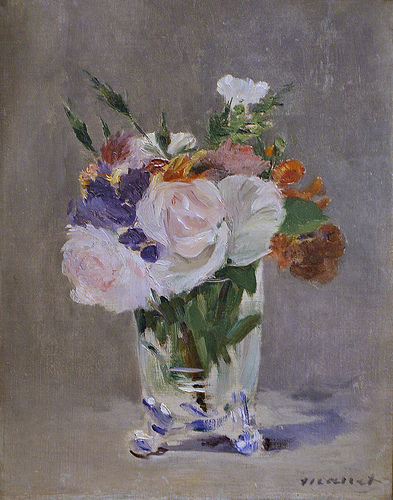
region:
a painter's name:
[301, 473, 379, 488]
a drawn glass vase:
[129, 262, 271, 449]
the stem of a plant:
[150, 296, 224, 406]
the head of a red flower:
[269, 224, 347, 282]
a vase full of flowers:
[49, 77, 347, 458]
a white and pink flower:
[74, 229, 147, 308]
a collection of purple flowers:
[77, 171, 146, 230]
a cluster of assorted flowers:
[96, 136, 266, 179]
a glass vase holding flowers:
[137, 271, 270, 450]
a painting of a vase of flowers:
[0, 2, 390, 497]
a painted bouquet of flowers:
[51, 67, 340, 370]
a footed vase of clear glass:
[120, 261, 273, 454]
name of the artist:
[298, 472, 387, 488]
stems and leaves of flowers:
[133, 272, 269, 409]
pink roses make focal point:
[60, 177, 225, 312]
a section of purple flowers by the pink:
[69, 164, 161, 270]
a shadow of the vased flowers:
[262, 365, 344, 453]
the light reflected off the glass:
[161, 354, 226, 403]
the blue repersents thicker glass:
[126, 383, 264, 462]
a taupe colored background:
[3, 0, 392, 457]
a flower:
[70, 235, 140, 302]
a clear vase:
[128, 312, 273, 462]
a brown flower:
[277, 234, 343, 286]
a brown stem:
[179, 334, 214, 404]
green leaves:
[76, 70, 139, 119]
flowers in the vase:
[97, 122, 277, 255]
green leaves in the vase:
[194, 300, 234, 351]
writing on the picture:
[288, 472, 377, 495]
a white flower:
[213, 65, 262, 109]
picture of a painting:
[17, 25, 383, 489]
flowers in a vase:
[21, 124, 342, 498]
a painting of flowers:
[19, 141, 390, 491]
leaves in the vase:
[150, 284, 291, 414]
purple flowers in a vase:
[92, 183, 116, 213]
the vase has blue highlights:
[122, 405, 274, 449]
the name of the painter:
[293, 466, 387, 490]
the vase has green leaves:
[191, 287, 224, 383]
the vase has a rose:
[145, 184, 227, 273]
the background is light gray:
[292, 291, 356, 404]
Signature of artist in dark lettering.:
[298, 469, 383, 493]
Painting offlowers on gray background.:
[0, 1, 389, 498]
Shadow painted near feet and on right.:
[131, 398, 382, 458]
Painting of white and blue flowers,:
[59, 173, 282, 309]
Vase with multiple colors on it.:
[128, 258, 263, 466]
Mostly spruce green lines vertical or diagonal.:
[141, 261, 262, 378]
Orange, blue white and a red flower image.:
[55, 76, 345, 317]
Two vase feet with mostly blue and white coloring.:
[124, 393, 266, 459]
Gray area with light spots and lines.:
[1, 1, 392, 70]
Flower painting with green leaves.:
[60, 67, 296, 182]